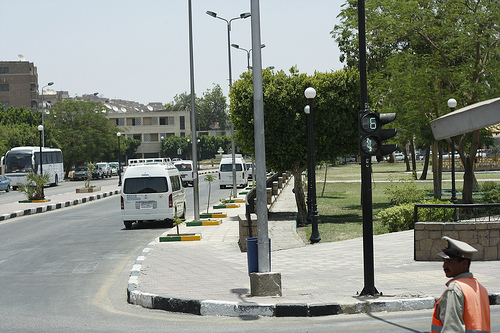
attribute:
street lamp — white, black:
[36, 120, 48, 206]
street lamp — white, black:
[116, 126, 123, 192]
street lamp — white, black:
[160, 132, 167, 165]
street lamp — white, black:
[185, 138, 190, 174]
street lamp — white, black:
[196, 134, 202, 169]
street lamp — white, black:
[307, 86, 319, 248]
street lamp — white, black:
[304, 104, 315, 244]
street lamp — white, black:
[445, 94, 462, 221]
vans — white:
[122, 152, 246, 227]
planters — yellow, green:
[20, 199, 51, 204]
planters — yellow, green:
[161, 236, 196, 243]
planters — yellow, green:
[186, 220, 224, 225]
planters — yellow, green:
[202, 213, 227, 218]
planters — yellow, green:
[214, 205, 241, 210]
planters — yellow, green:
[222, 200, 249, 203]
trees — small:
[24, 175, 49, 199]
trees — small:
[169, 204, 185, 238]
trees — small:
[201, 169, 214, 215]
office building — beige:
[46, 98, 193, 156]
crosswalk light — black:
[355, 107, 393, 164]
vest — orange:
[429, 278, 493, 332]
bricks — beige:
[177, 262, 216, 291]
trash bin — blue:
[243, 236, 277, 278]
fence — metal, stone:
[235, 168, 283, 253]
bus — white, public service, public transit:
[2, 142, 66, 191]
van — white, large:
[122, 154, 188, 224]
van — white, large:
[170, 157, 199, 187]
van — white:
[217, 153, 247, 190]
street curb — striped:
[124, 299, 427, 314]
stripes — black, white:
[153, 300, 282, 317]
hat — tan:
[437, 234, 480, 264]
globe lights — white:
[35, 125, 47, 133]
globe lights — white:
[115, 130, 124, 139]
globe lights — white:
[159, 136, 166, 143]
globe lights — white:
[186, 137, 191, 144]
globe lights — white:
[198, 139, 205, 145]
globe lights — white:
[303, 83, 320, 104]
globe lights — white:
[303, 103, 315, 117]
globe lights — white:
[447, 95, 459, 112]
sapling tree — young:
[245, 63, 354, 235]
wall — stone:
[416, 224, 499, 259]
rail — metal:
[416, 203, 500, 227]